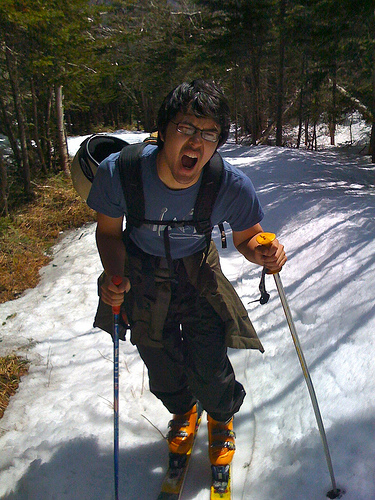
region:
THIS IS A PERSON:
[37, 71, 309, 482]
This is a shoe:
[200, 403, 243, 473]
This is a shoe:
[168, 399, 203, 454]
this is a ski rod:
[253, 202, 366, 494]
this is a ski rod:
[90, 258, 147, 498]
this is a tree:
[259, 16, 294, 159]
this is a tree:
[109, 26, 164, 196]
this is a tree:
[140, 5, 253, 142]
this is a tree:
[213, 12, 263, 142]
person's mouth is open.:
[175, 144, 199, 173]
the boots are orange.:
[155, 390, 235, 478]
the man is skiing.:
[66, 77, 347, 495]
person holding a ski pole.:
[247, 246, 364, 499]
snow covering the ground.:
[0, 126, 373, 498]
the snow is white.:
[2, 117, 373, 496]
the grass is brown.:
[1, 151, 87, 302]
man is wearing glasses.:
[166, 108, 220, 143]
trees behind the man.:
[0, 2, 371, 149]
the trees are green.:
[0, 2, 372, 145]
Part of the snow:
[312, 240, 343, 288]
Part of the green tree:
[31, 19, 77, 44]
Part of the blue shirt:
[155, 194, 164, 202]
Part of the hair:
[191, 89, 201, 92]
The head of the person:
[154, 71, 234, 186]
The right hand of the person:
[99, 271, 133, 308]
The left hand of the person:
[253, 234, 289, 276]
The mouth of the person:
[178, 149, 201, 176]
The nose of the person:
[188, 129, 205, 148]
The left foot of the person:
[205, 412, 237, 467]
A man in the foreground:
[62, 67, 350, 498]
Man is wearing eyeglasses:
[145, 73, 243, 190]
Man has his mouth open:
[170, 142, 205, 184]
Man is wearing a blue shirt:
[82, 141, 272, 273]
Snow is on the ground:
[2, 106, 373, 497]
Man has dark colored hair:
[136, 70, 251, 180]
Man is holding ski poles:
[79, 220, 356, 498]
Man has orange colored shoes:
[147, 393, 253, 473]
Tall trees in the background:
[0, 1, 370, 198]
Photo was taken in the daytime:
[1, 2, 371, 498]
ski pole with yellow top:
[238, 228, 359, 498]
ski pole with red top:
[97, 270, 145, 498]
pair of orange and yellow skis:
[152, 402, 233, 495]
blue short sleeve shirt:
[87, 135, 269, 279]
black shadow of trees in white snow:
[237, 188, 370, 445]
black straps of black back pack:
[98, 127, 231, 259]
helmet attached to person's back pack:
[63, 121, 134, 212]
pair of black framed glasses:
[160, 106, 226, 145]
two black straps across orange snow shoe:
[209, 423, 241, 453]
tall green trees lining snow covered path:
[2, 2, 373, 172]